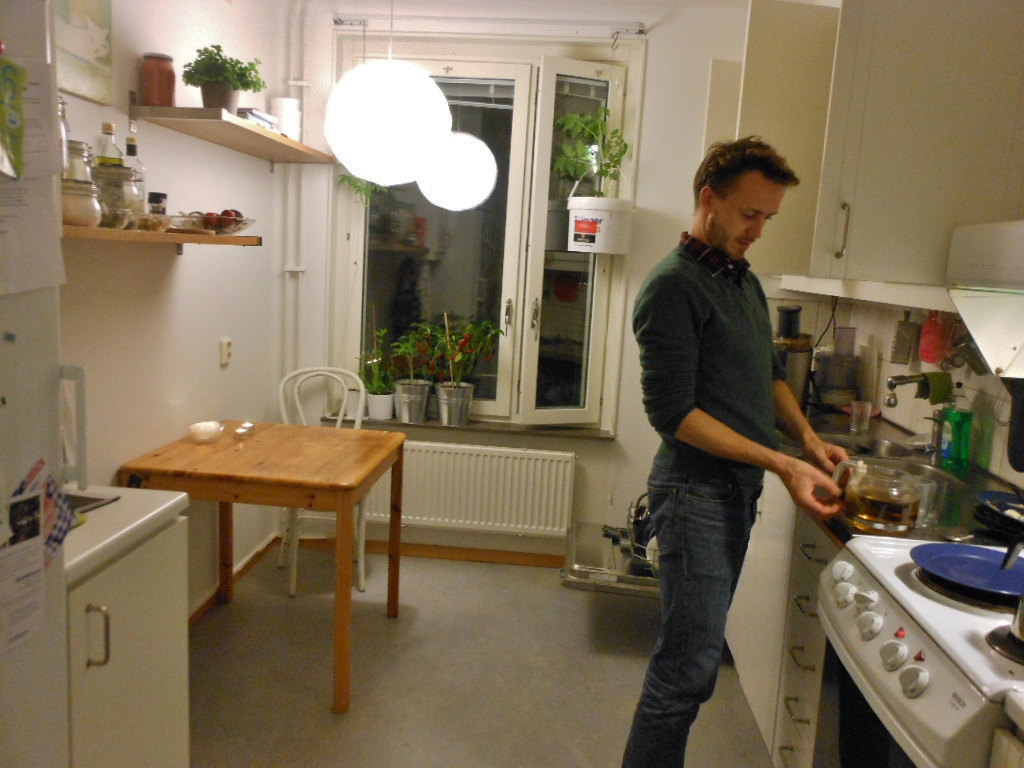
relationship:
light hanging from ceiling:
[324, 56, 452, 187] [45, 3, 751, 29]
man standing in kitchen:
[624, 123, 849, 762] [4, 1, 1023, 761]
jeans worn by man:
[625, 439, 769, 760] [624, 123, 849, 762]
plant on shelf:
[144, 27, 268, 123] [128, 99, 341, 177]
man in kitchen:
[624, 123, 849, 762] [4, 1, 1023, 761]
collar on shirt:
[677, 230, 755, 276] [630, 230, 790, 483]